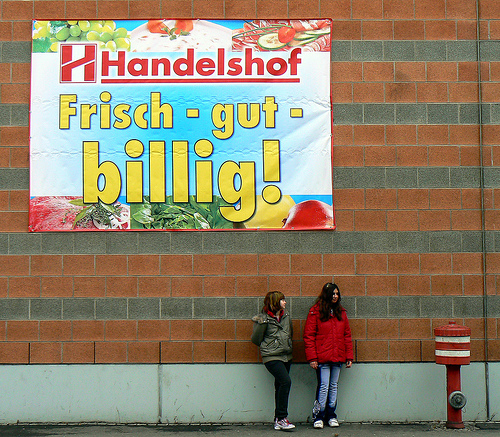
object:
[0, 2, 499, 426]
building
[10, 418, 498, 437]
asphalt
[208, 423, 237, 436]
ground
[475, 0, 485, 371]
seam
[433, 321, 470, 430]
hydrant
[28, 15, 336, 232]
banner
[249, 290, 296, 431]
girl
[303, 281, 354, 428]
girl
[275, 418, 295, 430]
tennis shoe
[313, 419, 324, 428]
tennis shoe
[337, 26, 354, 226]
wall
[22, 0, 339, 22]
brick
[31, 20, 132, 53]
grapes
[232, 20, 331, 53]
cucumber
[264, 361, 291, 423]
black pants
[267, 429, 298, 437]
sidewalk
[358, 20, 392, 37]
brick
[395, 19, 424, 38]
brick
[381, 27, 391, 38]
part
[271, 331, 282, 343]
part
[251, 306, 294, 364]
jacket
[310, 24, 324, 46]
part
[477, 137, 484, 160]
part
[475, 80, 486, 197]
pole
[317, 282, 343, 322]
hair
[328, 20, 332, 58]
edge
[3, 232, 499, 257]
gray bricks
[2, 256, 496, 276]
bricks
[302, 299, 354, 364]
jacket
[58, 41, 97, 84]
hogo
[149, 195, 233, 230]
spinach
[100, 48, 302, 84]
company name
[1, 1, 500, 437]
photo